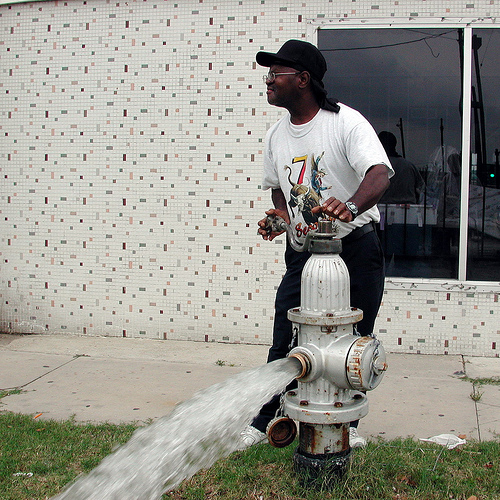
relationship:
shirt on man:
[244, 107, 399, 242] [254, 36, 401, 425]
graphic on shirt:
[284, 151, 341, 238] [228, 104, 381, 245]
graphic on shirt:
[282, 155, 328, 234] [260, 112, 391, 240]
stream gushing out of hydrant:
[45, 355, 303, 500] [278, 224, 374, 478]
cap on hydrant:
[263, 417, 299, 450] [261, 214, 384, 474]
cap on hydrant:
[341, 333, 387, 394] [261, 214, 384, 474]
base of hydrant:
[254, 403, 368, 480] [276, 211, 377, 496]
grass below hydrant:
[0, 409, 500, 499] [276, 207, 390, 476]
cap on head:
[256, 39, 328, 82] [258, 64, 326, 107]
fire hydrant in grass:
[264, 212, 388, 496] [210, 453, 488, 486]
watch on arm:
[344, 201, 358, 222] [340, 167, 387, 221]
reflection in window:
[374, 126, 456, 235] [323, 27, 497, 285]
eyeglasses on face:
[260, 68, 298, 82] [263, 53, 286, 108]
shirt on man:
[262, 101, 396, 253] [250, 31, 384, 412]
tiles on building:
[57, 69, 157, 152] [0, 0, 498, 359]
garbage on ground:
[419, 433, 467, 450] [18, 343, 494, 495]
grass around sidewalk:
[0, 409, 500, 499] [12, 331, 496, 417]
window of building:
[323, 27, 497, 285] [9, 10, 497, 359]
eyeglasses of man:
[262, 71, 300, 82] [235, 39, 395, 455]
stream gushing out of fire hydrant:
[45, 355, 303, 500] [278, 208, 385, 489]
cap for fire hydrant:
[266, 417, 297, 449] [278, 208, 385, 489]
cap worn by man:
[256, 39, 328, 82] [235, 39, 395, 455]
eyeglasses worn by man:
[262, 71, 300, 82] [235, 39, 395, 455]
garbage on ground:
[419, 433, 467, 450] [1, 330, 498, 499]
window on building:
[317, 28, 499, 283] [0, 0, 498, 359]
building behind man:
[0, 0, 498, 359] [235, 39, 395, 455]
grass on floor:
[1, 409, 498, 499] [0, 330, 498, 498]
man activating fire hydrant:
[235, 39, 395, 455] [278, 208, 385, 489]